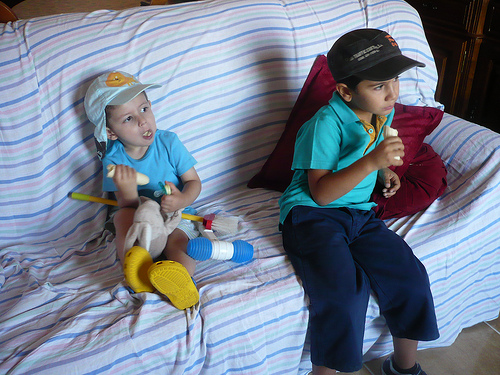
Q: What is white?
A: Hat.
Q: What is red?
A: Pillow.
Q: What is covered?
A: Couch.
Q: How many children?
A: Two.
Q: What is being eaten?
A: Bananas.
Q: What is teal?
A: Shirt.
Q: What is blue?
A: Pants.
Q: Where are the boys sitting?
A: On a couch.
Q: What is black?
A: Hat.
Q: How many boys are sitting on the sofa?
A: 2.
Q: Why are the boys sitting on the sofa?
A: Watch television.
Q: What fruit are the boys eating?
A: Bananas.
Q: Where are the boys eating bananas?
A: Living area.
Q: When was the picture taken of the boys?
A: Mid afternoon.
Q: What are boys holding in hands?
A: Bananas.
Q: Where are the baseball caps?
A: On boy's heads.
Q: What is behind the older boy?
A: Red sofa pillows.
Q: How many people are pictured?
A: Two.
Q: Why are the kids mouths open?
A: Eating.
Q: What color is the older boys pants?
A: Blue.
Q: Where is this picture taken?
A: Living room.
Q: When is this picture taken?
A: While eating.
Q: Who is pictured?
A: Two little boys.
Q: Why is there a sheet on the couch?
A: Protection.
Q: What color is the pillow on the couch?
A: Red.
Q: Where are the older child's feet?
A: Floor.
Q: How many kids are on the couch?
A: Two.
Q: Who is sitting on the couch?
A: Children.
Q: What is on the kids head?
A: Hats.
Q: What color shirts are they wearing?
A: Light blue.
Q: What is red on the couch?
A: Pillow.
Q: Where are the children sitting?
A: The couch.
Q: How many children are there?
A: 2.